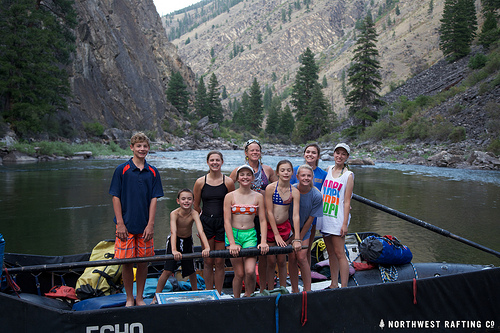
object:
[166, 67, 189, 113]
evergreen tree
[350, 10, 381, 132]
evergreen tree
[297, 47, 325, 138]
evergreen tree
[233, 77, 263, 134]
evergreen tree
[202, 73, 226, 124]
evergreen tree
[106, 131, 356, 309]
people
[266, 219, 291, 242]
shorts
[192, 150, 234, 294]
person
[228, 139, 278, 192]
person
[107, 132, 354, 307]
group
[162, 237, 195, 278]
swim trunks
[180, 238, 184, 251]
drawstrings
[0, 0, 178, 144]
mountain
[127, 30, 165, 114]
stone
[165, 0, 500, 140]
trees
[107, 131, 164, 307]
boy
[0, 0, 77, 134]
vegetation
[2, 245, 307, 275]
black oar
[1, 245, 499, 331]
raft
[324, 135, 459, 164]
shore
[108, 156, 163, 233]
polo shirt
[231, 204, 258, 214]
bikini top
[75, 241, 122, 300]
duffel bag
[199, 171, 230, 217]
shirt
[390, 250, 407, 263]
blue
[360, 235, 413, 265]
bag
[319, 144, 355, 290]
girl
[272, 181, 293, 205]
bikini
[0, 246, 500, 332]
boat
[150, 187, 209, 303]
boy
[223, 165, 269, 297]
girl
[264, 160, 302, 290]
girl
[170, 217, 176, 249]
arms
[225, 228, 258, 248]
green shorts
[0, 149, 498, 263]
river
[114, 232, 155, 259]
checkered shorts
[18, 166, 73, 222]
water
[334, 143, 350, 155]
cap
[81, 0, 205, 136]
cliff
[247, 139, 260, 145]
sunglasses